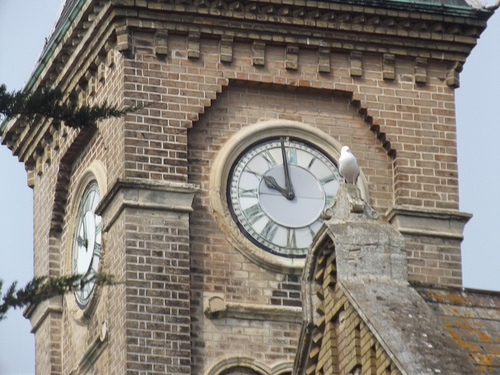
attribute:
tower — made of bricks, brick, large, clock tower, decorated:
[3, 0, 494, 375]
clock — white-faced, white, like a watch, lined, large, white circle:
[228, 142, 366, 260]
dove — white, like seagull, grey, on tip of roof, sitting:
[338, 146, 362, 184]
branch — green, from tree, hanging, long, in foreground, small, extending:
[2, 83, 155, 125]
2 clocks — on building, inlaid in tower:
[55, 121, 367, 310]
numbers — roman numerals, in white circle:
[244, 150, 279, 241]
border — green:
[1, 0, 101, 124]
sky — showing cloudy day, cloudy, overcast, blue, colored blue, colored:
[0, 8, 42, 47]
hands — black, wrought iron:
[265, 141, 294, 201]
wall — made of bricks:
[129, 56, 192, 371]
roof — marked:
[2, 0, 494, 158]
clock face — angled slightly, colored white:
[65, 179, 111, 307]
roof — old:
[412, 277, 498, 374]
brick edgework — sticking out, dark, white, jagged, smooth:
[125, 8, 487, 87]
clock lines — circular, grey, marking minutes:
[232, 163, 244, 223]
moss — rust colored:
[436, 289, 466, 304]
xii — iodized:
[283, 147, 301, 166]